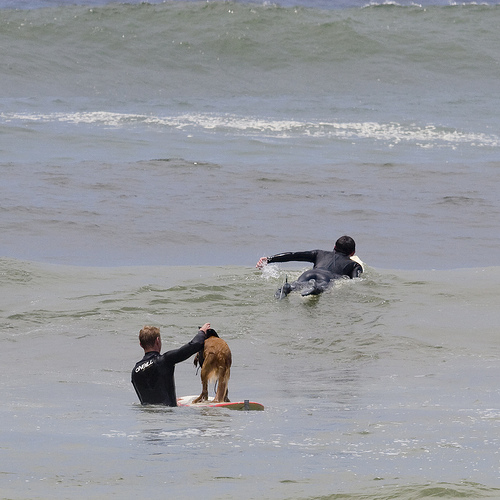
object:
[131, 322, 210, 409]
man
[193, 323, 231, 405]
dog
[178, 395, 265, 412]
surfboard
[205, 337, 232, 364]
fur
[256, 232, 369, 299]
man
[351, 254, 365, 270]
surfboard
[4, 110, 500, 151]
wave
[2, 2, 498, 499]
ocean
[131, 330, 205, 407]
wet suit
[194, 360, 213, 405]
leg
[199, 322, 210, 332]
hand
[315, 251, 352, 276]
back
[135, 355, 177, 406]
torso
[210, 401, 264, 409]
stripe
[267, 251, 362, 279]
shirt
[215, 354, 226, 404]
tail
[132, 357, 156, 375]
name of brand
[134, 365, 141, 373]
white letters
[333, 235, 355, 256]
hair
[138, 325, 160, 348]
hair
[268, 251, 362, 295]
wet suit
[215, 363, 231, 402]
leg